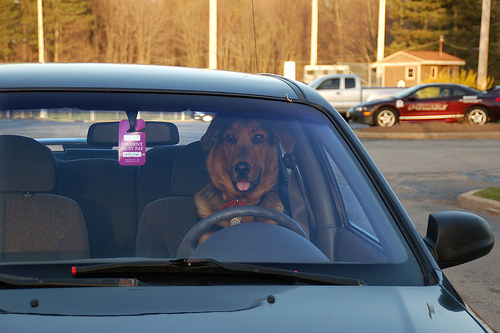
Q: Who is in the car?
A: Dog.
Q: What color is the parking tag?
A: Purple.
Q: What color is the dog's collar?
A: Red.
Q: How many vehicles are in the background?
A: Two.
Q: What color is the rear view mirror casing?
A: Black.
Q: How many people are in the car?
A: None.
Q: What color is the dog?
A: Brown.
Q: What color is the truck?
A: Silver.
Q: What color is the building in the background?
A: Brown.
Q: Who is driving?
A: A dog.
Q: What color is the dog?
A: Black and brown.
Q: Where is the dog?
A: Behind the driving wheel.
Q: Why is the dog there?
A: To make a funny photo.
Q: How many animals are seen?
A: Just 1 dog.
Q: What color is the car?
A: Black.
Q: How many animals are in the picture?
A: One.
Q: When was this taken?
A: Daytime.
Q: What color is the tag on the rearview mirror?
A: Purple.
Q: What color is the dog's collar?
A: Red.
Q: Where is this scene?
A: A parking lot.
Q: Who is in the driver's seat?
A: A dog.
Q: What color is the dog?
A: Brown.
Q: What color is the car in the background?
A: Red.